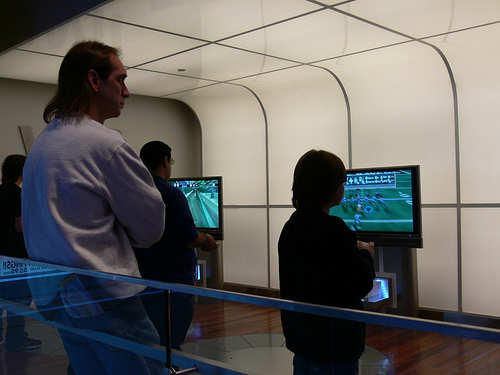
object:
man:
[20, 40, 178, 373]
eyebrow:
[113, 72, 127, 79]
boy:
[277, 148, 378, 374]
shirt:
[279, 211, 371, 351]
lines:
[452, 85, 464, 320]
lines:
[262, 115, 272, 287]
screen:
[178, 179, 219, 231]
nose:
[121, 82, 132, 99]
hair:
[294, 150, 339, 206]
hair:
[36, 38, 124, 127]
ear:
[86, 70, 98, 89]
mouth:
[103, 95, 130, 115]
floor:
[2, 299, 497, 372]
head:
[50, 40, 130, 121]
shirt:
[22, 115, 165, 303]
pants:
[42, 292, 155, 373]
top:
[62, 269, 364, 374]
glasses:
[168, 158, 178, 167]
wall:
[180, 34, 500, 344]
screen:
[335, 168, 417, 238]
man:
[138, 135, 226, 345]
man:
[0, 153, 47, 350]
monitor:
[319, 165, 411, 242]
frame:
[162, 177, 224, 236]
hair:
[4, 152, 26, 178]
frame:
[342, 163, 422, 248]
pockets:
[58, 278, 107, 320]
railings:
[2, 251, 483, 371]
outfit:
[274, 210, 377, 372]